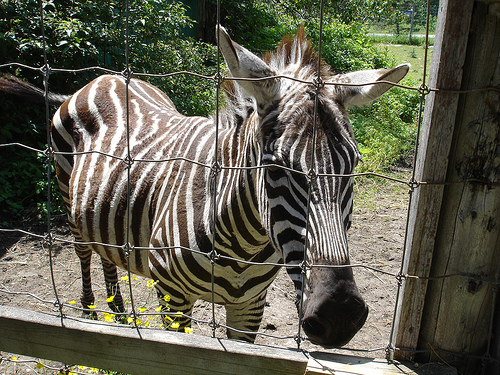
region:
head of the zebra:
[235, 34, 421, 296]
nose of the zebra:
[278, 258, 380, 356]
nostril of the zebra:
[303, 308, 334, 340]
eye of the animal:
[251, 129, 318, 192]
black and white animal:
[43, 119, 212, 274]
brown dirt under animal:
[366, 193, 398, 249]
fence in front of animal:
[66, 41, 353, 300]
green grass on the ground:
[398, 43, 438, 78]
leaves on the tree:
[79, 36, 168, 69]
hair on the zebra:
[268, 21, 330, 63]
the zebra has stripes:
[22, 41, 494, 287]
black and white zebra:
[222, 44, 394, 364]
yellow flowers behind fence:
[49, 237, 192, 348]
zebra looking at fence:
[238, 52, 392, 342]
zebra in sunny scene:
[204, 54, 379, 371]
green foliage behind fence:
[239, 9, 435, 54]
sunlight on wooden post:
[9, 235, 131, 364]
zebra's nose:
[270, 217, 371, 369]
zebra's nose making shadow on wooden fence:
[272, 235, 378, 369]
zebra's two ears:
[183, 38, 406, 131]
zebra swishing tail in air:
[5, 37, 175, 219]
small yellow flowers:
[56, 249, 213, 350]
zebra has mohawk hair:
[230, 27, 346, 113]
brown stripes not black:
[113, 101, 250, 201]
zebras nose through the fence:
[290, 252, 375, 352]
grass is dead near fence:
[13, 213, 426, 348]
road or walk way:
[363, 20, 448, 51]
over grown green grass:
[356, 27, 437, 47]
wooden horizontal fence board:
[0, 282, 300, 372]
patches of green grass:
[352, 167, 405, 208]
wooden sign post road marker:
[396, 5, 426, 42]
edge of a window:
[421, 187, 422, 215]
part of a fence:
[173, 303, 196, 343]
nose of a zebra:
[333, 245, 342, 265]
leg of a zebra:
[177, 240, 186, 307]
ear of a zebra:
[256, 70, 283, 95]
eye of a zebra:
[267, 134, 285, 184]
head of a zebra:
[311, 124, 323, 130]